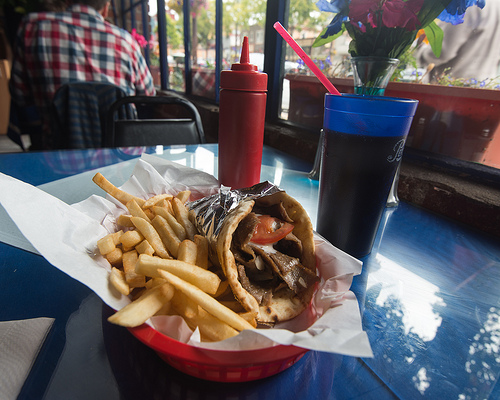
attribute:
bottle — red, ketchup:
[214, 32, 271, 191]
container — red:
[92, 186, 322, 385]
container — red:
[100, 184, 350, 387]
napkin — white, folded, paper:
[0, 314, 56, 397]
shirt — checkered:
[5, 5, 156, 148]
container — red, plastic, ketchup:
[213, 32, 270, 185]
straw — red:
[269, 19, 344, 97]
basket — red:
[100, 182, 349, 390]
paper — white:
[0, 146, 381, 369]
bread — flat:
[213, 187, 319, 322]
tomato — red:
[246, 210, 297, 246]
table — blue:
[5, 144, 495, 398]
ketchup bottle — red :
[216, 34, 263, 194]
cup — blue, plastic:
[321, 89, 420, 267]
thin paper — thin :
[6, 149, 376, 369]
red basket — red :
[87, 286, 323, 388]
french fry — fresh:
[153, 266, 257, 332]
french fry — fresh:
[127, 214, 172, 258]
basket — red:
[128, 321, 310, 383]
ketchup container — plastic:
[214, 34, 268, 189]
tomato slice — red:
[249, 211, 293, 245]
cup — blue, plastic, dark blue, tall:
[315, 90, 418, 260]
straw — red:
[271, 19, 372, 132]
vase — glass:
[348, 51, 400, 209]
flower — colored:
[379, 1, 425, 34]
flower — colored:
[439, 0, 484, 25]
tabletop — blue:
[1, 140, 481, 397]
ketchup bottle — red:
[214, 34, 269, 188]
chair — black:
[101, 92, 207, 146]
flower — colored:
[316, 0, 348, 29]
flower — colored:
[349, 0, 381, 33]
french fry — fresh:
[131, 249, 221, 295]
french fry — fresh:
[104, 278, 174, 329]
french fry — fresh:
[109, 263, 131, 295]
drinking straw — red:
[271, 20, 371, 134]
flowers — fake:
[307, 0, 483, 86]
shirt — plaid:
[5, 3, 158, 134]